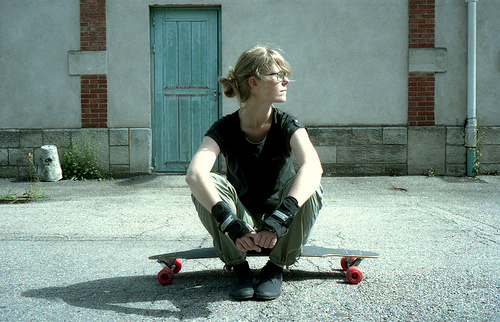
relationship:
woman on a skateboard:
[184, 42, 324, 302] [159, 242, 381, 267]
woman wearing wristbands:
[181, 42, 328, 302] [203, 194, 301, 244]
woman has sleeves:
[181, 42, 328, 302] [200, 111, 300, 143]